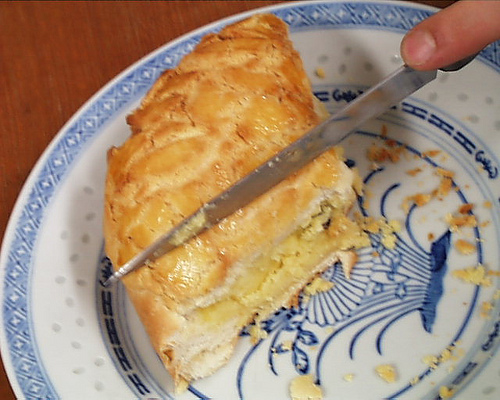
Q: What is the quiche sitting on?
A: Plate.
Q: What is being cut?
A: Pie.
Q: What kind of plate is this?
A: China.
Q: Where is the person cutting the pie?
A: Off screen.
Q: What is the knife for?
A: Cutting the cake.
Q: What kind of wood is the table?
A: Maple.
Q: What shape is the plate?
A: Circle.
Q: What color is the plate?
A: Blue and white.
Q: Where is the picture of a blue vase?
A: On the plate.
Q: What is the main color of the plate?
A: Blue and white.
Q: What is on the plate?
A: Food.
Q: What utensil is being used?
A: Knife.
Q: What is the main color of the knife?
A: Silver.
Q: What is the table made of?
A: Wood.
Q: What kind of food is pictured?
A: Cake.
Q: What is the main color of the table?
A: Brown.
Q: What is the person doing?
A: Cutting the cake.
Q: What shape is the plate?
A: Round.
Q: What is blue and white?
A: The plate.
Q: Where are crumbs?
A: On the plate.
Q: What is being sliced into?
A: A pie.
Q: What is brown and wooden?
A: Table.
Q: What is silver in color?
A: Knife.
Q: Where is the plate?
A: On table.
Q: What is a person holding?
A: A knife.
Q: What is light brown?
A: Pie.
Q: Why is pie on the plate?
A: To be eaten.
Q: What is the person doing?
A: Slicing a piece of pie.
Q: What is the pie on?
A: A plate.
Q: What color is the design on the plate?
A: Blue.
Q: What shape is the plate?
A: Round.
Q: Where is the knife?
A: On the food.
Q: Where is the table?
A: Under the plate.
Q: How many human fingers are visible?
A: One.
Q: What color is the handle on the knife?
A: Black.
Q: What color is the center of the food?
A: Yellow.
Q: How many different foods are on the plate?
A: One.